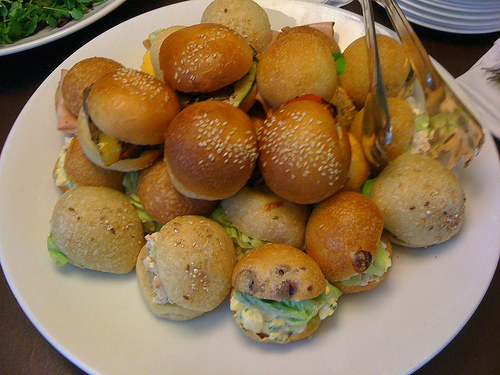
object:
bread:
[48, 183, 143, 275]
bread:
[233, 243, 331, 341]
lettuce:
[233, 289, 340, 328]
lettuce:
[343, 240, 394, 287]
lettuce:
[409, 95, 470, 145]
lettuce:
[208, 205, 268, 250]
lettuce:
[47, 234, 68, 268]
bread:
[87, 70, 177, 145]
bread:
[371, 157, 464, 246]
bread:
[258, 100, 350, 205]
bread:
[161, 98, 257, 200]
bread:
[302, 189, 392, 296]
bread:
[158, 23, 255, 95]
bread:
[257, 29, 338, 111]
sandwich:
[134, 211, 233, 323]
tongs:
[357, 0, 483, 174]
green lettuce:
[0, 0, 90, 55]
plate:
[0, 11, 105, 53]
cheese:
[95, 136, 120, 166]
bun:
[73, 68, 181, 171]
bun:
[163, 100, 258, 200]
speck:
[106, 225, 117, 236]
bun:
[50, 182, 135, 271]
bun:
[259, 97, 352, 206]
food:
[44, 3, 481, 338]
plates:
[375, 0, 499, 37]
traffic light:
[134, 50, 156, 80]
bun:
[157, 21, 255, 101]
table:
[0, 269, 77, 373]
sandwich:
[223, 179, 311, 244]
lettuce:
[124, 172, 163, 226]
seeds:
[191, 142, 211, 152]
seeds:
[199, 118, 211, 131]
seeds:
[213, 122, 223, 137]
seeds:
[223, 140, 234, 160]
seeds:
[227, 145, 243, 157]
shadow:
[231, 322, 316, 355]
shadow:
[173, 302, 233, 334]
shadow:
[346, 283, 392, 300]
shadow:
[397, 236, 463, 260]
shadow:
[55, 259, 134, 285]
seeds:
[202, 148, 220, 170]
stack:
[404, 0, 493, 37]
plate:
[4, 0, 500, 372]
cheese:
[136, 42, 157, 80]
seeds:
[258, 106, 345, 180]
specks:
[254, 102, 344, 191]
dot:
[275, 278, 302, 299]